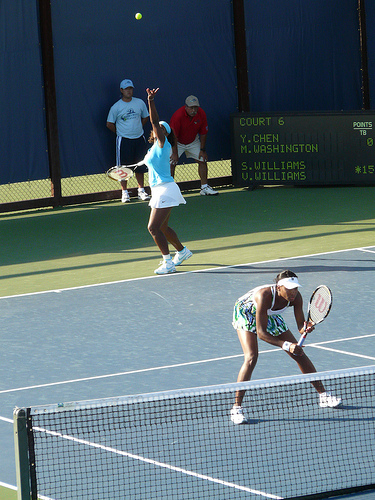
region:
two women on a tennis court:
[112, 80, 346, 416]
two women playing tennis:
[98, 75, 343, 437]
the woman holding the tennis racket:
[85, 73, 213, 278]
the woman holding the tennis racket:
[213, 258, 354, 417]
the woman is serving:
[90, 72, 208, 286]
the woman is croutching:
[208, 243, 366, 417]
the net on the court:
[4, 354, 372, 495]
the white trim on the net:
[17, 361, 374, 430]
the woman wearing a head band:
[148, 112, 180, 138]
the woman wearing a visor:
[273, 264, 302, 294]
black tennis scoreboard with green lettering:
[228, 109, 373, 189]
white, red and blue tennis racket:
[296, 282, 333, 350]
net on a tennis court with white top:
[12, 384, 368, 494]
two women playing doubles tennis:
[104, 84, 351, 427]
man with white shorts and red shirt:
[167, 93, 220, 198]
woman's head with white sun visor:
[272, 268, 302, 303]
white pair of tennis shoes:
[228, 390, 343, 424]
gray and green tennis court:
[1, 253, 218, 388]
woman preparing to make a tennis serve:
[100, 83, 200, 274]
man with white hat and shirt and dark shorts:
[103, 78, 151, 201]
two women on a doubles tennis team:
[76, 26, 369, 433]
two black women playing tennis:
[98, 7, 370, 430]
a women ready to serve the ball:
[98, 3, 204, 280]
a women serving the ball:
[65, 6, 239, 279]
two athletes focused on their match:
[66, 56, 372, 429]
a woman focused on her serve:
[102, 9, 218, 287]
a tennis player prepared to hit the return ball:
[193, 252, 355, 432]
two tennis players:
[96, 68, 372, 482]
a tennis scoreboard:
[226, 98, 372, 199]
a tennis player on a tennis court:
[227, 269, 343, 425]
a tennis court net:
[10, 365, 371, 495]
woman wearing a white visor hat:
[276, 273, 302, 289]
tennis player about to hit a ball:
[106, 10, 195, 274]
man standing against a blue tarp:
[109, 80, 151, 204]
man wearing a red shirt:
[173, 107, 207, 142]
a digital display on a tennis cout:
[232, 113, 373, 188]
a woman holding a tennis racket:
[258, 268, 331, 354]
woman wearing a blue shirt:
[143, 137, 176, 185]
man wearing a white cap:
[121, 79, 136, 89]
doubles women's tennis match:
[1, 32, 374, 497]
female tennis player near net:
[0, 266, 374, 495]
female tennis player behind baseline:
[2, 85, 373, 301]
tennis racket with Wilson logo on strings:
[295, 279, 332, 344]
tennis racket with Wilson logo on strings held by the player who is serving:
[105, 159, 143, 182]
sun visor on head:
[275, 268, 301, 301]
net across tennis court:
[13, 362, 371, 497]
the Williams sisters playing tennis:
[104, 84, 342, 424]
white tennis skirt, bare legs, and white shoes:
[141, 208, 191, 275]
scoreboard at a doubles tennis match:
[233, 112, 373, 183]